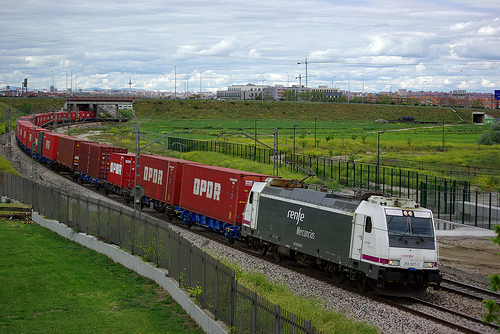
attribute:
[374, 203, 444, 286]
front — white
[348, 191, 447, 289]
cabin — white, grey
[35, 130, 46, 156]
car — green, red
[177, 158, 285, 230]
car — red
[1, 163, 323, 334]
fence — gray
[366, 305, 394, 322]
gravel — brown, grey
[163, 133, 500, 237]
fence — black, gray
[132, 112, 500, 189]
grass — green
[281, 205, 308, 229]
lettering — white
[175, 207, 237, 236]
bottom — blue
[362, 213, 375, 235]
window — black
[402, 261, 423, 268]
number — black, white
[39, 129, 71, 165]
cargo container — red